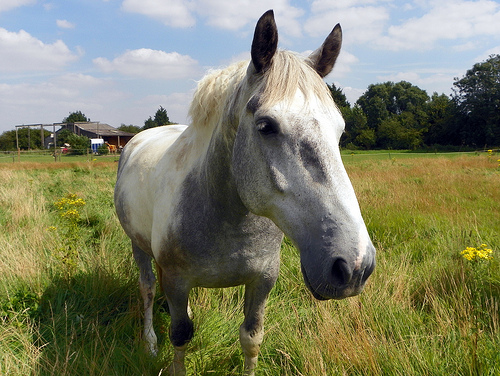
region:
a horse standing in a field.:
[100, 10, 410, 374]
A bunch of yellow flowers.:
[438, 203, 496, 275]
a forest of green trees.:
[0, 48, 497, 150]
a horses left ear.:
[292, 17, 375, 79]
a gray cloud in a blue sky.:
[93, 33, 213, 96]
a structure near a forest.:
[45, 123, 132, 170]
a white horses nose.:
[279, 215, 402, 318]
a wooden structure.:
[0, 111, 126, 164]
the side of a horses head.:
[202, 3, 284, 129]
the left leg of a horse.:
[227, 258, 292, 374]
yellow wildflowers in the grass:
[450, 227, 494, 274]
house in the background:
[13, 120, 128, 158]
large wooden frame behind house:
[7, 119, 69, 158]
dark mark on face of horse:
[290, 132, 329, 192]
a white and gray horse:
[109, 10, 407, 375]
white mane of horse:
[177, 34, 331, 144]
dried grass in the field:
[2, 165, 52, 371]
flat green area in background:
[347, 147, 459, 159]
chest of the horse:
[165, 220, 273, 290]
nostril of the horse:
[320, 254, 354, 292]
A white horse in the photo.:
[110, 7, 400, 372]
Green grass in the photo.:
[404, 312, 486, 370]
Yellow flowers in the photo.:
[457, 238, 491, 268]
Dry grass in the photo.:
[17, 186, 44, 233]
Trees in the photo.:
[397, 87, 435, 140]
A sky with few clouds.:
[87, 22, 161, 84]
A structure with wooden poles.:
[4, 118, 63, 160]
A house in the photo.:
[83, 121, 128, 151]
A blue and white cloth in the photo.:
[86, 137, 106, 154]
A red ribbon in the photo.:
[59, 142, 72, 157]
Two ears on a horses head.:
[250, 10, 343, 80]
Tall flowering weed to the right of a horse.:
[460, 241, 494, 366]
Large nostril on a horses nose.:
[326, 254, 351, 290]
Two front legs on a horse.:
[160, 275, 271, 374]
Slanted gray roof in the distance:
[72, 119, 137, 141]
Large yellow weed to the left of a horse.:
[51, 192, 83, 296]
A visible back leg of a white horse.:
[125, 243, 158, 357]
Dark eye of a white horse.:
[257, 116, 284, 141]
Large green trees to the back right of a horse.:
[359, 78, 445, 149]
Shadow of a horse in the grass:
[32, 266, 142, 374]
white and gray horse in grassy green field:
[109, 6, 381, 374]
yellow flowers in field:
[451, 223, 498, 374]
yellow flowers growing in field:
[48, 189, 93, 341]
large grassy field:
[0, 146, 498, 374]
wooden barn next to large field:
[46, 117, 138, 159]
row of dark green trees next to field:
[206, 51, 498, 154]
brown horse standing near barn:
[102, 140, 120, 156]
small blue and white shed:
[80, 136, 109, 155]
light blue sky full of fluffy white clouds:
[0, 0, 499, 149]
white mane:
[183, 44, 345, 129]